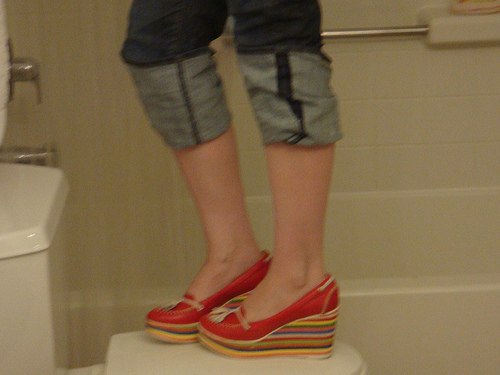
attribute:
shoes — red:
[142, 253, 342, 354]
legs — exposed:
[125, 8, 339, 320]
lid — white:
[103, 328, 362, 373]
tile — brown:
[40, 116, 184, 223]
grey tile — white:
[352, 55, 491, 183]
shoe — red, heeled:
[198, 271, 340, 359]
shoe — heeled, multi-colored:
[143, 250, 273, 345]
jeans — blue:
[115, 14, 353, 171]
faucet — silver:
[1, 145, 62, 167]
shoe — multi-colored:
[197, 280, 335, 358]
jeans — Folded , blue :
[118, 1, 343, 151]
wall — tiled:
[199, 32, 499, 189]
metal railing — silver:
[321, 23, 431, 38]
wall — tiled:
[367, 16, 477, 225]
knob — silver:
[5, 51, 52, 108]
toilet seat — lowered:
[102, 314, 365, 374]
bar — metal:
[220, 25, 425, 42]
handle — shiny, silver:
[5, 40, 47, 114]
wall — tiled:
[373, 92, 459, 163]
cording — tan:
[207, 305, 239, 322]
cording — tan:
[156, 297, 182, 309]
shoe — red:
[103, 206, 395, 373]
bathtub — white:
[63, 186, 496, 373]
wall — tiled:
[380, 65, 440, 186]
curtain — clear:
[21, 0, 219, 360]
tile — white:
[372, 92, 422, 149]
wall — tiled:
[319, 37, 497, 280]